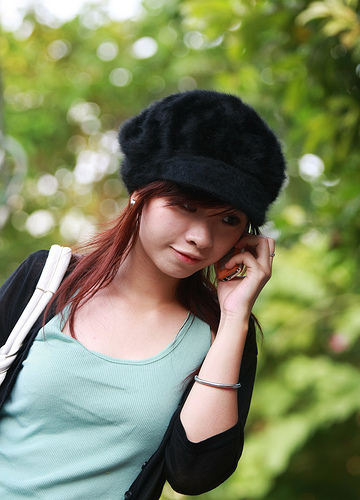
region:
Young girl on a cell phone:
[1, 73, 333, 492]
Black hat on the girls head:
[113, 86, 286, 272]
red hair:
[58, 216, 142, 329]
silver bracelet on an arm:
[178, 356, 269, 441]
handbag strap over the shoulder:
[0, 239, 72, 391]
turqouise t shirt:
[2, 292, 211, 499]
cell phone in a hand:
[213, 220, 284, 312]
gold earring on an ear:
[111, 171, 155, 252]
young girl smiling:
[118, 90, 259, 292]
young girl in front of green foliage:
[2, 8, 301, 487]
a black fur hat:
[118, 89, 288, 226]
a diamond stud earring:
[129, 197, 136, 204]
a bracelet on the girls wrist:
[193, 373, 241, 389]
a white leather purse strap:
[0, 244, 72, 383]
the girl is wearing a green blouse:
[0, 308, 210, 499]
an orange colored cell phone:
[213, 261, 243, 279]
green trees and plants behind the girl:
[284, 0, 359, 497]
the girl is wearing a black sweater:
[154, 425, 245, 498]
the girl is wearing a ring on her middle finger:
[268, 249, 274, 258]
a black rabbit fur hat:
[119, 88, 286, 225]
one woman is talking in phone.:
[15, 136, 263, 423]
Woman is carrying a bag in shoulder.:
[1, 238, 71, 361]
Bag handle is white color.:
[0, 250, 88, 364]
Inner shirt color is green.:
[35, 387, 109, 476]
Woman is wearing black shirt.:
[6, 265, 57, 344]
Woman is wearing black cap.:
[132, 111, 269, 203]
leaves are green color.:
[298, 222, 355, 297]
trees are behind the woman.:
[59, 118, 348, 473]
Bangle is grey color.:
[187, 362, 246, 407]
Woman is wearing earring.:
[114, 183, 152, 227]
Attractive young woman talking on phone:
[0, 91, 288, 499]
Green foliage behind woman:
[0, 0, 358, 498]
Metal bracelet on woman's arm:
[190, 371, 243, 391]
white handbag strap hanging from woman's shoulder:
[0, 240, 74, 384]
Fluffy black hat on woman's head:
[115, 87, 285, 231]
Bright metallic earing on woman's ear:
[128, 193, 140, 208]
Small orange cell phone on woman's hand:
[213, 234, 251, 283]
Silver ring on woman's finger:
[266, 248, 277, 257]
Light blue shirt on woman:
[0, 280, 213, 498]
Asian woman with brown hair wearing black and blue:
[0, 89, 288, 498]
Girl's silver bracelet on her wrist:
[189, 369, 246, 396]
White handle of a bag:
[0, 241, 79, 379]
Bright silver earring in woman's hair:
[127, 195, 138, 210]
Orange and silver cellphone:
[216, 224, 264, 284]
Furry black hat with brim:
[109, 84, 296, 228]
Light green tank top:
[0, 288, 212, 498]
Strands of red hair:
[41, 190, 154, 338]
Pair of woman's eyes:
[171, 188, 247, 229]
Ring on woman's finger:
[267, 250, 277, 259]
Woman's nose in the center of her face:
[186, 213, 215, 255]